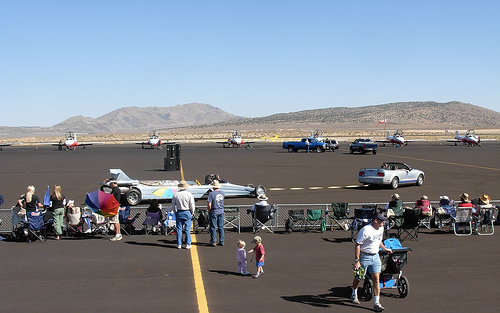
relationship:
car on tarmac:
[354, 158, 428, 193] [7, 142, 498, 309]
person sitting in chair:
[453, 189, 474, 211] [450, 207, 474, 237]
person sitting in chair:
[432, 193, 454, 213] [435, 205, 455, 229]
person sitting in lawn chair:
[249, 189, 273, 207] [242, 205, 278, 237]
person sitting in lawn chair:
[145, 197, 168, 230] [140, 207, 169, 239]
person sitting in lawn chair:
[62, 195, 87, 235] [62, 211, 85, 237]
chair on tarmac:
[450, 207, 474, 237] [5, 143, 494, 270]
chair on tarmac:
[435, 205, 455, 229] [5, 143, 494, 270]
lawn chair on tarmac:
[242, 205, 278, 237] [5, 143, 494, 270]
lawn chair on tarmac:
[140, 207, 169, 239] [5, 143, 494, 270]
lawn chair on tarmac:
[62, 211, 85, 237] [5, 143, 494, 270]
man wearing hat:
[172, 180, 194, 251] [171, 178, 192, 191]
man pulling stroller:
[349, 214, 394, 312] [355, 230, 411, 303]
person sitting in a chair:
[387, 191, 405, 210] [384, 212, 407, 229]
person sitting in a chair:
[424, 189, 435, 206] [410, 208, 435, 226]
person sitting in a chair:
[438, 195, 457, 215] [435, 210, 455, 228]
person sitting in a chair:
[458, 192, 475, 209] [453, 204, 475, 234]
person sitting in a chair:
[480, 193, 491, 206] [477, 206, 498, 235]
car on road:
[357, 158, 425, 189] [0, 139, 495, 311]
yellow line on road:
[178, 151, 217, 311] [0, 139, 495, 311]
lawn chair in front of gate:
[285, 207, 305, 229] [274, 200, 286, 226]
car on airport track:
[357, 158, 425, 189] [13, 140, 498, 310]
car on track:
[103, 168, 258, 198] [5, 139, 499, 306]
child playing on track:
[236, 240, 249, 275] [7, 226, 497, 311]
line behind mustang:
[253, 175, 424, 200] [360, 160, 429, 184]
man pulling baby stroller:
[349, 214, 394, 312] [380, 236, 410, 301]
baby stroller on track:
[380, 236, 410, 301] [7, 226, 497, 311]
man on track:
[349, 214, 394, 312] [7, 226, 497, 311]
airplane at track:
[38, 131, 106, 151] [5, 139, 499, 306]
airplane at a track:
[213, 125, 259, 153] [227, 155, 332, 174]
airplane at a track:
[387, 130, 408, 149] [5, 139, 499, 306]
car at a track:
[98, 168, 267, 205] [241, 155, 336, 191]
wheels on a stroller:
[361, 276, 416, 299] [360, 233, 420, 300]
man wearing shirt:
[345, 206, 391, 297] [343, 232, 402, 267]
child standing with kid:
[236, 240, 249, 275] [248, 231, 268, 281]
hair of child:
[234, 235, 246, 247] [233, 232, 252, 283]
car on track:
[357, 158, 425, 189] [11, 133, 491, 204]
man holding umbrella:
[108, 192, 120, 237] [82, 186, 119, 221]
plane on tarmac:
[47, 128, 97, 165] [7, 142, 498, 309]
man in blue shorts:
[349, 214, 394, 312] [358, 251, 383, 276]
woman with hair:
[50, 186, 68, 239] [54, 183, 64, 202]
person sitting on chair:
[474, 193, 493, 217] [472, 206, 497, 236]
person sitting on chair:
[458, 192, 475, 209] [450, 207, 474, 237]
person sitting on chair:
[438, 195, 457, 215] [435, 205, 455, 229]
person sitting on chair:
[416, 195, 433, 216] [415, 200, 435, 230]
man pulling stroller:
[349, 214, 394, 312] [362, 236, 410, 300]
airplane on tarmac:
[23, 132, 123, 159] [7, 142, 498, 309]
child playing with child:
[247, 233, 269, 281] [230, 237, 250, 277]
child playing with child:
[232, 240, 252, 276] [247, 235, 268, 280]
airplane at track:
[130, 132, 180, 150] [1, 139, 498, 236]